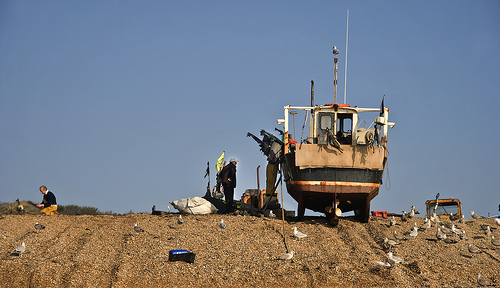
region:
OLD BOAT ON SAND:
[265, 105, 415, 229]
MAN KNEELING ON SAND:
[35, 181, 60, 211]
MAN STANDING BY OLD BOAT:
[212, 151, 234, 211]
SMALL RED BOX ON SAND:
[370, 202, 387, 224]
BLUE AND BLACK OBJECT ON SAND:
[159, 244, 202, 261]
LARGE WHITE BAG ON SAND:
[169, 194, 219, 216]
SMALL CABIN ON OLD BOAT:
[315, 103, 352, 145]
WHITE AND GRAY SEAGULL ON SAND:
[380, 248, 405, 265]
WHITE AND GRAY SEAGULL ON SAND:
[293, 226, 310, 240]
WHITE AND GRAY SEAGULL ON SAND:
[275, 245, 298, 261]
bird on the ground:
[288, 220, 309, 245]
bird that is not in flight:
[271, 245, 295, 263]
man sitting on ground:
[38, 185, 59, 213]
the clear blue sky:
[7, 8, 226, 116]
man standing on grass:
[211, 150, 243, 204]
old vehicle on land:
[276, 53, 387, 213]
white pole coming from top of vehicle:
[339, 0, 358, 105]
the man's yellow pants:
[39, 202, 61, 213]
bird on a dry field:
[214, 210, 242, 239]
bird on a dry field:
[288, 215, 311, 258]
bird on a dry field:
[360, 254, 395, 281]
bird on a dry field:
[403, 222, 420, 245]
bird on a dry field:
[398, 196, 425, 221]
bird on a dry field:
[432, 215, 468, 247]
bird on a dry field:
[453, 234, 484, 261]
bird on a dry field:
[465, 261, 487, 286]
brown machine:
[285, 92, 383, 200]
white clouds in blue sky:
[411, 32, 456, 70]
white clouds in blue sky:
[435, 79, 483, 127]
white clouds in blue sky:
[412, 75, 459, 129]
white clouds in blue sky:
[391, 8, 456, 55]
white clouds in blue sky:
[8, 31, 55, 71]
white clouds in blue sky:
[175, 52, 223, 97]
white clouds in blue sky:
[110, 96, 150, 124]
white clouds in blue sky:
[68, 63, 109, 100]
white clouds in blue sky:
[218, 45, 260, 75]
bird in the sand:
[288, 222, 308, 241]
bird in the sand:
[276, 247, 296, 264]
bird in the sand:
[369, 253, 394, 272]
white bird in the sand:
[401, 220, 421, 240]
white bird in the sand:
[409, 196, 419, 222]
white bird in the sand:
[421, 214, 432, 236]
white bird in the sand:
[382, 213, 398, 228]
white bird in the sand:
[469, 270, 492, 287]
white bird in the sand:
[462, 239, 484, 257]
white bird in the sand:
[489, 234, 499, 246]